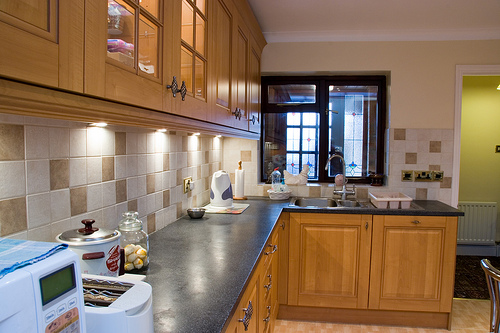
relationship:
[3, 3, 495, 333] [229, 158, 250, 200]
scene shows a paper towel holder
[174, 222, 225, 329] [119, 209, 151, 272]
counter holds glass jar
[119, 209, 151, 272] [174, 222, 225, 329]
glass jar sitting on counter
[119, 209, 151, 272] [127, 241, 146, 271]
glass jar has round items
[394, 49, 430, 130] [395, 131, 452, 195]
wall has tiles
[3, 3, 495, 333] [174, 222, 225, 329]
scene shows black counter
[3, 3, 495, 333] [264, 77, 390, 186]
scene shows windows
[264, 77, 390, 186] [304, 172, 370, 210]
windows are over sink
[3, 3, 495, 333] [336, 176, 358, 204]
kitchen has faucet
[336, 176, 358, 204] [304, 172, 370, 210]
faucet part of sink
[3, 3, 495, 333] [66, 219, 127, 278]
scene has rice cooker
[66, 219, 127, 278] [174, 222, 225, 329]
rice cooker on counter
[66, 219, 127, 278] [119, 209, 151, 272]
rice cooker next to glass jar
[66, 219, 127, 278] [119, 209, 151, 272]
rice cooker to right of glass jar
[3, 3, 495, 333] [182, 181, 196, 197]
scene shows outlet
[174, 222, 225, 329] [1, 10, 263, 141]
counter below cabinets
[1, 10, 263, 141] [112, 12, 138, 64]
cabinets have glass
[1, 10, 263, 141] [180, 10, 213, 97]
cabinets have windows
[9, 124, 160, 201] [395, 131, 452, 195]
wall has tiles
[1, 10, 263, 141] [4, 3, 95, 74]
cabinets are made with wood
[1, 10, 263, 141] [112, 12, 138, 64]
cabinets are made with glass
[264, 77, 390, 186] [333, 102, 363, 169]
window shows outside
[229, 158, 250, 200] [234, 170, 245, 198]
paper towel holder holds paper towel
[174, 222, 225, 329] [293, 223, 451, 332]
counter above woden cabinets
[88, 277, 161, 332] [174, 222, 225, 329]
white toaster rests atop counter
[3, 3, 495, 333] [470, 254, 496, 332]
scene shows a chair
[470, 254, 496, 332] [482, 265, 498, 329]
chair shows back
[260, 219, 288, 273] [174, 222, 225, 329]
drawer below counter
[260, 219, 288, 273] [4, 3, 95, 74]
drawer made of wood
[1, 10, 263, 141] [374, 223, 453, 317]
cabinets have doors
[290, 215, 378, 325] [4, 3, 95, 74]
cabinet doors are made of wood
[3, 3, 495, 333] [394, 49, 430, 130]
scene shows a wall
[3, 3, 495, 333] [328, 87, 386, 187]
scene shows window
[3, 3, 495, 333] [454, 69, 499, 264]
scene shows a door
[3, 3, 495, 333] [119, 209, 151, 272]
scene shows a container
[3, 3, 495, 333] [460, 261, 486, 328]
scene shows floor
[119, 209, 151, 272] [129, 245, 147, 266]
cannister shows edibles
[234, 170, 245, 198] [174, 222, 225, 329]
paper towel on counter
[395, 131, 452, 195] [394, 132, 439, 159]
tiles on wall are beautiful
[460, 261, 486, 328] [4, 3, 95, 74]
floor might be wood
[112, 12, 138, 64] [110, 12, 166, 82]
glass in cabinets lovely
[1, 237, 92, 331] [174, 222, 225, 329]
microwave on top of counter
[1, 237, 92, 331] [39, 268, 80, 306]
microwave has digital readout area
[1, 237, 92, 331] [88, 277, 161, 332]
microwave to left of toaster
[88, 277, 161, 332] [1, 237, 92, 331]
white toaster to left of microwave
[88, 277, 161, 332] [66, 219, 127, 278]
white toaster to right of rice cooker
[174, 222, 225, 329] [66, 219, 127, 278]
counter holding crockpot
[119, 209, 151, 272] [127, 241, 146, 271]
glass jar holding snacks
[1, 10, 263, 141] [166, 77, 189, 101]
cabinets have knobs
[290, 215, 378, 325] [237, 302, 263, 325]
cabinets have handles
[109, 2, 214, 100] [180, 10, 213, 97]
two cabinets have window panes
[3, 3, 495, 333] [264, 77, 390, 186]
kitchen has two windows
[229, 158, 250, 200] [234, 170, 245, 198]
paper towel holder holding paper towel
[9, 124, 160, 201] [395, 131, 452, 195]
black splash has tiles